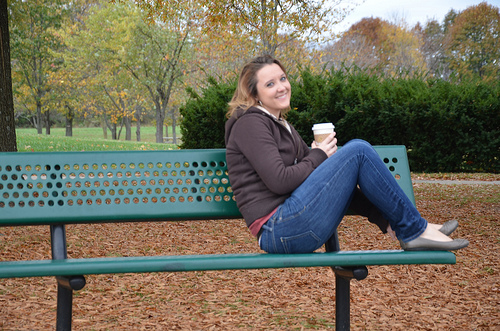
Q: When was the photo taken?
A: Daytime.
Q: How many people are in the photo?
A: One.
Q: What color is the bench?
A: Greens.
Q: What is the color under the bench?
A: Brown.